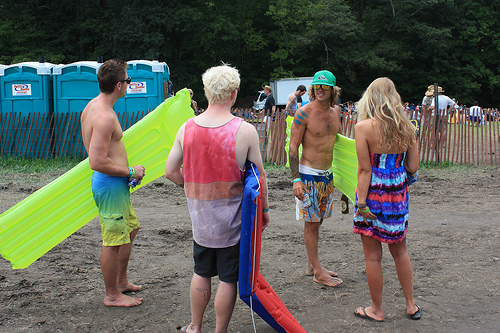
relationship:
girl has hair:
[340, 72, 426, 321] [351, 71, 419, 144]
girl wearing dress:
[340, 72, 426, 321] [351, 143, 412, 236]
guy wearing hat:
[286, 65, 356, 304] [305, 64, 345, 93]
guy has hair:
[168, 60, 273, 330] [201, 61, 241, 104]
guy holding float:
[76, 56, 347, 333] [1, 81, 205, 269]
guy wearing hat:
[286, 65, 356, 304] [308, 63, 339, 91]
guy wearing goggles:
[286, 65, 356, 304] [314, 83, 334, 94]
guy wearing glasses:
[76, 56, 347, 333] [118, 78, 134, 86]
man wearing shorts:
[76, 54, 159, 312] [82, 155, 144, 250]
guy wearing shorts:
[286, 65, 356, 304] [292, 160, 334, 230]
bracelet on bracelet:
[355, 199, 370, 216] [355, 207, 371, 214]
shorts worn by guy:
[85, 173, 147, 255] [76, 56, 163, 311]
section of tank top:
[189, 125, 239, 185] [180, 114, 248, 250]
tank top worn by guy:
[180, 114, 248, 250] [168, 60, 273, 330]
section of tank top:
[175, 174, 245, 208] [180, 114, 248, 250]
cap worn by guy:
[310, 69, 337, 86] [286, 65, 356, 304]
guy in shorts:
[286, 65, 356, 304] [291, 164, 346, 235]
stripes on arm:
[287, 105, 305, 136] [279, 100, 319, 201]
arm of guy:
[279, 100, 319, 201] [286, 65, 356, 304]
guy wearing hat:
[286, 65, 356, 304] [306, 64, 337, 97]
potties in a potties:
[4, 51, 179, 181] [4, 59, 166, 159]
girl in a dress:
[340, 72, 426, 321] [350, 143, 420, 243]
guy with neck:
[168, 60, 273, 330] [193, 103, 237, 121]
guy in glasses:
[76, 56, 347, 333] [118, 78, 134, 86]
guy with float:
[76, 56, 347, 333] [1, 81, 205, 269]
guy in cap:
[286, 65, 356, 304] [304, 65, 338, 95]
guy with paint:
[286, 65, 356, 304] [289, 105, 314, 137]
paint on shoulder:
[289, 105, 314, 137] [285, 102, 321, 130]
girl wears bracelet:
[340, 72, 426, 321] [354, 206, 370, 217]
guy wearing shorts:
[168, 60, 273, 330] [192, 240, 239, 285]